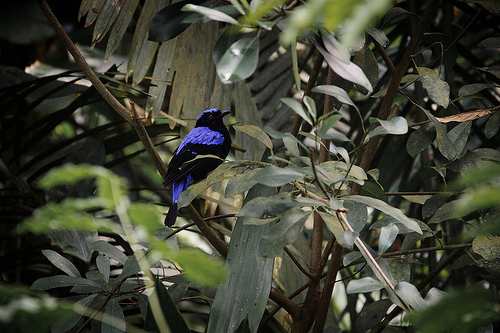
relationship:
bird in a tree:
[155, 101, 245, 235] [2, 6, 496, 324]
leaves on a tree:
[22, 174, 292, 329] [2, 6, 496, 324]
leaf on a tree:
[90, 295, 130, 331] [2, 6, 496, 324]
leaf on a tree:
[213, 157, 298, 206] [2, 6, 496, 324]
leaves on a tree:
[294, 164, 477, 276] [2, 6, 496, 324]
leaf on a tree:
[370, 217, 404, 262] [2, 6, 496, 324]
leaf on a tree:
[370, 110, 411, 140] [2, 6, 496, 324]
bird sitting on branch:
[159, 108, 234, 227] [82, 55, 232, 218]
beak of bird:
[224, 108, 236, 126] [161, 103, 228, 230]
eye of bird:
[208, 114, 214, 119] [164, 106, 231, 231]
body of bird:
[166, 135, 231, 193] [162, 99, 229, 222]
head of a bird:
[197, 105, 227, 134] [159, 108, 234, 227]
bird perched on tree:
[159, 108, 234, 227] [52, 2, 383, 331]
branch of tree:
[61, 28, 302, 315] [60, 18, 392, 320]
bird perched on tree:
[159, 108, 234, 227] [60, 18, 392, 320]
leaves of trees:
[373, 22, 484, 232] [36, 5, 470, 330]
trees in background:
[36, 5, 470, 330] [75, 3, 484, 173]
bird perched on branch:
[159, 108, 234, 227] [74, 43, 157, 186]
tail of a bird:
[164, 170, 185, 232] [159, 108, 234, 227]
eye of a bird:
[208, 108, 220, 125] [159, 108, 234, 227]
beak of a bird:
[220, 110, 232, 118] [159, 108, 234, 227]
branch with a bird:
[61, 28, 159, 152] [159, 108, 234, 227]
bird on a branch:
[159, 108, 234, 227] [61, 28, 159, 152]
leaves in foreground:
[31, 174, 227, 324] [3, 191, 270, 330]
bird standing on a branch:
[159, 108, 234, 227] [36, 3, 157, 148]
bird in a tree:
[159, 108, 234, 227] [56, 1, 431, 328]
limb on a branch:
[149, 152, 201, 222] [44, 5, 163, 175]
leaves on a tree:
[244, 164, 396, 276] [56, 1, 431, 328]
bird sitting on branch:
[159, 108, 234, 227] [59, 27, 302, 319]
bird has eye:
[159, 108, 234, 227] [207, 113, 216, 121]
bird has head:
[159, 108, 234, 227] [194, 104, 232, 129]